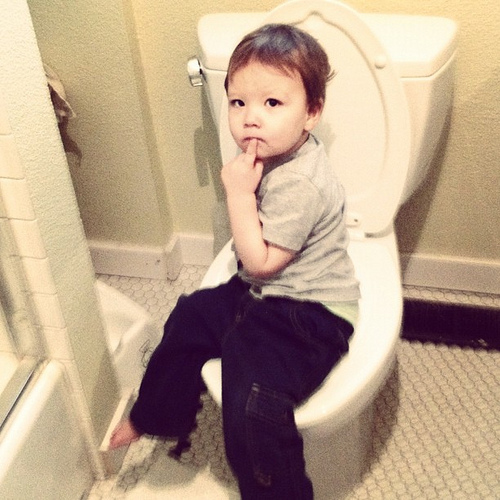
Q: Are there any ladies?
A: No, there are no ladies.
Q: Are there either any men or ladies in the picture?
A: No, there are no ladies or men.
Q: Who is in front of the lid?
A: The boy is in front of the lid.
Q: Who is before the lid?
A: The boy is in front of the lid.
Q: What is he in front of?
A: The boy is in front of the lid.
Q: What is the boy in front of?
A: The boy is in front of the lid.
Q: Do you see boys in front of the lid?
A: Yes, there is a boy in front of the lid.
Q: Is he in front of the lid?
A: Yes, the boy is in front of the lid.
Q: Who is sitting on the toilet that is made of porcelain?
A: The boy is sitting on the toilet.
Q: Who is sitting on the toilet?
A: The boy is sitting on the toilet.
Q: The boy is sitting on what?
A: The boy is sitting on the toilet.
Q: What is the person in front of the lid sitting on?
A: The boy is sitting on the toilet.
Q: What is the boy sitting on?
A: The boy is sitting on the toilet.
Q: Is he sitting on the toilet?
A: Yes, the boy is sitting on the toilet.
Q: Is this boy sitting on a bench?
A: No, the boy is sitting on the toilet.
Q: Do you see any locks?
A: No, there are no locks.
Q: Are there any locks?
A: No, there are no locks.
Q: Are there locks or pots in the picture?
A: No, there are no locks or pots.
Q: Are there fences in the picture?
A: No, there are no fences.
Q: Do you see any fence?
A: No, there are no fences.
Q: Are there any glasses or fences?
A: No, there are no fences or glasses.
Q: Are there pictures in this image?
A: No, there are no pictures.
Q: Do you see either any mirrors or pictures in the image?
A: No, there are no pictures or mirrors.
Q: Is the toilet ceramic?
A: Yes, the toilet is ceramic.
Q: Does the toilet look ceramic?
A: Yes, the toilet is ceramic.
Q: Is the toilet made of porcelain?
A: Yes, the toilet is made of porcelain.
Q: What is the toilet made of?
A: The toilet is made of porcelain.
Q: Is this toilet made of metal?
A: No, the toilet is made of porcelain.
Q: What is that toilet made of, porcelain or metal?
A: The toilet is made of porcelain.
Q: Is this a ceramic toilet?
A: Yes, this is a ceramic toilet.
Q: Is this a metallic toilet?
A: No, this is a ceramic toilet.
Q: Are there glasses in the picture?
A: No, there are no glasses.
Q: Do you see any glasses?
A: No, there are no glasses.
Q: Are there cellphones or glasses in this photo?
A: No, there are no glasses or cellphones.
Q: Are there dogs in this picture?
A: No, there are no dogs.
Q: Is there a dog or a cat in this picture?
A: No, there are no dogs or cats.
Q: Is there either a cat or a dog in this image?
A: No, there are no dogs or cats.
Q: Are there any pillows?
A: No, there are no pillows.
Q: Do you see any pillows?
A: No, there are no pillows.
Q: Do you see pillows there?
A: No, there are no pillows.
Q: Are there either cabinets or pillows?
A: No, there are no pillows or cabinets.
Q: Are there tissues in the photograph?
A: No, there are no tissues.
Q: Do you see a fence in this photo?
A: No, there are no fences.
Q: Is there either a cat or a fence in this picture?
A: No, there are no fences or cats.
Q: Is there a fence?
A: No, there are no fences.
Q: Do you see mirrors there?
A: No, there are no mirrors.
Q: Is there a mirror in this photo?
A: No, there are no mirrors.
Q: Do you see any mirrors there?
A: No, there are no mirrors.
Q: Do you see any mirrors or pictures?
A: No, there are no mirrors or pictures.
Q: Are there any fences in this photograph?
A: No, there are no fences.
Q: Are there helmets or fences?
A: No, there are no fences or helmets.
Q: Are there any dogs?
A: No, there are no dogs.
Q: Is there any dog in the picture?
A: No, there are no dogs.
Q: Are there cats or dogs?
A: No, there are no dogs or cats.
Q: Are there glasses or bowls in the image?
A: No, there are no glasses or bowls.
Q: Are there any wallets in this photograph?
A: No, there are no wallets.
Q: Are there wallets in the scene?
A: No, there are no wallets.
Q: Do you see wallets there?
A: No, there are no wallets.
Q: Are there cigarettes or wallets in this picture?
A: No, there are no wallets or cigarettes.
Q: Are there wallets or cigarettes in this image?
A: No, there are no wallets or cigarettes.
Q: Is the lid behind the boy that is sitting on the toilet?
A: Yes, the lid is behind the boy.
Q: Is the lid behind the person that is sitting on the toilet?
A: Yes, the lid is behind the boy.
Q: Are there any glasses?
A: No, there are no glasses.